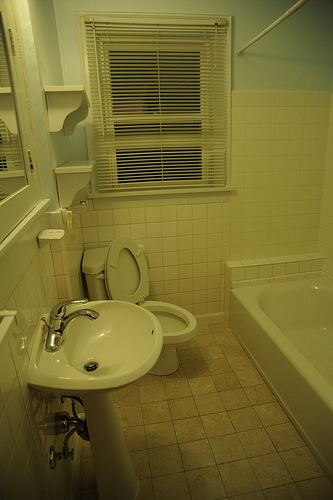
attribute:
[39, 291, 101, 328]
faucet — silver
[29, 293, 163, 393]
sink — white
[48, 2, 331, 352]
wall — tiled, white, tan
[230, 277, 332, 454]
bathtub — white, large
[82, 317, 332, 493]
floor — tiled, brown, tan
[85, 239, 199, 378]
toilet — white, porcelain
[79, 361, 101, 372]
drain — silver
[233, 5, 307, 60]
shower curtain rod — thin, white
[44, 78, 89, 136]
shelf — white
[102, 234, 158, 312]
toilet seat — up